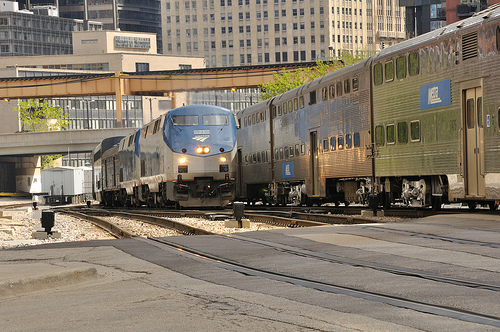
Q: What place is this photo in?
A: It is at the road.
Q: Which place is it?
A: It is a road.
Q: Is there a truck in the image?
A: Yes, there is a truck.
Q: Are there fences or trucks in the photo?
A: Yes, there is a truck.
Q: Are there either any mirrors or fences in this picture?
A: No, there are no fences or mirrors.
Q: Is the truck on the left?
A: Yes, the truck is on the left of the image.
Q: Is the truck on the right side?
A: No, the truck is on the left of the image.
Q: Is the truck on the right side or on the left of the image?
A: The truck is on the left of the image.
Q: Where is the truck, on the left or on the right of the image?
A: The truck is on the left of the image.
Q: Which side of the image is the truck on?
A: The truck is on the left of the image.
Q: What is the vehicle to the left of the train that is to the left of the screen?
A: The vehicle is a truck.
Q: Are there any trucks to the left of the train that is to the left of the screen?
A: Yes, there is a truck to the left of the train.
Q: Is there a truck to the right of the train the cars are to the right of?
A: No, the truck is to the left of the train.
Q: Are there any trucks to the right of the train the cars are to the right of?
A: No, the truck is to the left of the train.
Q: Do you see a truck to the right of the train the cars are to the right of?
A: No, the truck is to the left of the train.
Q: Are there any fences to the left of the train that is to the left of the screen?
A: No, there is a truck to the left of the train.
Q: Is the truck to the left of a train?
A: Yes, the truck is to the left of a train.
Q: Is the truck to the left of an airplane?
A: No, the truck is to the left of a train.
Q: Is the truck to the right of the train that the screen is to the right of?
A: No, the truck is to the left of the train.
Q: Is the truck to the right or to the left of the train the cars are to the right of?
A: The truck is to the left of the train.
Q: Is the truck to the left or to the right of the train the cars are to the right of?
A: The truck is to the left of the train.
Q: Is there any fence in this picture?
A: No, there are no fences.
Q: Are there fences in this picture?
A: No, there are no fences.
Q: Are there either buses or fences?
A: No, there are no fences or buses.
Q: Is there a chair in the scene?
A: No, there are no chairs.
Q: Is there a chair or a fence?
A: No, there are no chairs or fences.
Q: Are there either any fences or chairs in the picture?
A: No, there are no chairs or fences.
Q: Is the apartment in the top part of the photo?
A: Yes, the apartment is in the top of the image.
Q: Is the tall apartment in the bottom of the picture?
A: No, the apartment is in the top of the image.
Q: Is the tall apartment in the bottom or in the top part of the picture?
A: The apartment is in the top of the image.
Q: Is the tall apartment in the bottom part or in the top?
A: The apartment is in the top of the image.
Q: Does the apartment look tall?
A: Yes, the apartment is tall.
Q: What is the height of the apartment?
A: The apartment is tall.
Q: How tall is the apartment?
A: The apartment is tall.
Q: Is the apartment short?
A: No, the apartment is tall.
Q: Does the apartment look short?
A: No, the apartment is tall.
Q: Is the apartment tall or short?
A: The apartment is tall.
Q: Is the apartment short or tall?
A: The apartment is tall.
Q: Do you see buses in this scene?
A: No, there are no buses.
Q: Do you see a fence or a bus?
A: No, there are no buses or fences.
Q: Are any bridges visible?
A: Yes, there is a bridge.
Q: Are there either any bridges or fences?
A: Yes, there is a bridge.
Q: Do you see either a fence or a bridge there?
A: Yes, there is a bridge.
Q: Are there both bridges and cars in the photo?
A: Yes, there are both a bridge and a car.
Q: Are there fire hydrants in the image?
A: No, there are no fire hydrants.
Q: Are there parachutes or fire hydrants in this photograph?
A: No, there are no fire hydrants or parachutes.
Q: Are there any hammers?
A: No, there are no hammers.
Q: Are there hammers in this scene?
A: No, there are no hammers.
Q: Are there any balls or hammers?
A: No, there are no hammers or balls.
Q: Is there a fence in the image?
A: No, there are no fences.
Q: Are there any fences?
A: No, there are no fences.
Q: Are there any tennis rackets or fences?
A: No, there are no fences or tennis rackets.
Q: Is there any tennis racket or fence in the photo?
A: No, there are no fences or rackets.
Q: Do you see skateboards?
A: No, there are no skateboards.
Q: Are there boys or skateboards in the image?
A: No, there are no skateboards or boys.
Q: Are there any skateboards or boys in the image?
A: No, there are no skateboards or boys.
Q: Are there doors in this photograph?
A: Yes, there is a door.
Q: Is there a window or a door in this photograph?
A: Yes, there is a door.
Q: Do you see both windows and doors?
A: Yes, there are both a door and a window.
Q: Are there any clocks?
A: No, there are no clocks.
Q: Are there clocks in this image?
A: No, there are no clocks.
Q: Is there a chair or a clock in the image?
A: No, there are no clocks or chairs.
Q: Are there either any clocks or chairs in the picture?
A: No, there are no clocks or chairs.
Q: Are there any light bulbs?
A: No, there are no light bulbs.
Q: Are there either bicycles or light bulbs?
A: No, there are no light bulbs or bicycles.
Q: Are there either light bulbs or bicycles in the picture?
A: No, there are no light bulbs or bicycles.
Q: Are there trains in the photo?
A: Yes, there are trains.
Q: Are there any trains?
A: Yes, there are trains.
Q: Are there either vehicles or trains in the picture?
A: Yes, there are trains.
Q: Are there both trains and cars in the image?
A: Yes, there are both trains and a car.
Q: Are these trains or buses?
A: These are trains.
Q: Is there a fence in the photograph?
A: No, there are no fences.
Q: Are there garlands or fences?
A: No, there are no fences or garlands.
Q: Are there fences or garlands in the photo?
A: No, there are no fences or garlands.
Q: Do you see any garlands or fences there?
A: No, there are no fences or garlands.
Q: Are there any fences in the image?
A: No, there are no fences.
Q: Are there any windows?
A: Yes, there are windows.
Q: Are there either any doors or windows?
A: Yes, there are windows.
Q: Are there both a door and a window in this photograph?
A: Yes, there are both a window and a door.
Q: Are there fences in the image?
A: No, there are no fences.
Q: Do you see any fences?
A: No, there are no fences.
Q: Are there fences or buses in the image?
A: No, there are no fences or buses.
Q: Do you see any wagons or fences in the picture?
A: No, there are no fences or wagons.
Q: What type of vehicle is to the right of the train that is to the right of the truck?
A: The vehicles are cars.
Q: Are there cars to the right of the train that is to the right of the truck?
A: Yes, there are cars to the right of the train.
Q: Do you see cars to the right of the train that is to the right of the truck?
A: Yes, there are cars to the right of the train.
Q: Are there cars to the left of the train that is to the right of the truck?
A: No, the cars are to the right of the train.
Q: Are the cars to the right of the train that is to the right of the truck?
A: Yes, the cars are to the right of the train.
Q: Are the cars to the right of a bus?
A: No, the cars are to the right of the train.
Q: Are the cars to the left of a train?
A: No, the cars are to the right of a train.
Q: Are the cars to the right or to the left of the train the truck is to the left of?
A: The cars are to the right of the train.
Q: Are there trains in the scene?
A: Yes, there is a train.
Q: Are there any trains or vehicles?
A: Yes, there is a train.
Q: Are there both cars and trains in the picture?
A: Yes, there are both a train and a car.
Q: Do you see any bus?
A: No, there are no buses.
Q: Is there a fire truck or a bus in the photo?
A: No, there are no buses or fire trucks.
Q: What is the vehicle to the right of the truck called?
A: The vehicle is a train.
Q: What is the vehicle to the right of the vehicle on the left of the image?
A: The vehicle is a train.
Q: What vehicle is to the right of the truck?
A: The vehicle is a train.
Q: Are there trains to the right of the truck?
A: Yes, there is a train to the right of the truck.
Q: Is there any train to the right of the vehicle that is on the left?
A: Yes, there is a train to the right of the truck.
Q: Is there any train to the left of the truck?
A: No, the train is to the right of the truck.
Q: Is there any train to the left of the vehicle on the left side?
A: No, the train is to the right of the truck.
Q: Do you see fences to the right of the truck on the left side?
A: No, there is a train to the right of the truck.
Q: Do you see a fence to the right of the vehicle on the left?
A: No, there is a train to the right of the truck.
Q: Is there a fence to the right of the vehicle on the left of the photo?
A: No, there is a train to the right of the truck.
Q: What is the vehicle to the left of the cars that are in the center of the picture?
A: The vehicle is a train.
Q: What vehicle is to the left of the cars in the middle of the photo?
A: The vehicle is a train.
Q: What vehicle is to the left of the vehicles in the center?
A: The vehicle is a train.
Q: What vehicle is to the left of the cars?
A: The vehicle is a train.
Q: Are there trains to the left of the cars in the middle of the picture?
A: Yes, there is a train to the left of the cars.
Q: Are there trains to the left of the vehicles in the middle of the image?
A: Yes, there is a train to the left of the cars.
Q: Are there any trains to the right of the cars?
A: No, the train is to the left of the cars.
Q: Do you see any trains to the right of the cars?
A: No, the train is to the left of the cars.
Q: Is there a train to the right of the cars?
A: No, the train is to the left of the cars.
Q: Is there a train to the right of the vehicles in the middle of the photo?
A: No, the train is to the left of the cars.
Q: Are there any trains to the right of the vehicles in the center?
A: No, the train is to the left of the cars.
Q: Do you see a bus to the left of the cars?
A: No, there is a train to the left of the cars.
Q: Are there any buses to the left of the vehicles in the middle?
A: No, there is a train to the left of the cars.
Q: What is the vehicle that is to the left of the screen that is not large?
A: The vehicle is a train.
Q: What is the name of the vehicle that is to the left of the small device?
A: The vehicle is a train.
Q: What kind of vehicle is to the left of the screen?
A: The vehicle is a train.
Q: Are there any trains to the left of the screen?
A: Yes, there is a train to the left of the screen.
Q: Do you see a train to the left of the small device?
A: Yes, there is a train to the left of the screen.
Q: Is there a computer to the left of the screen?
A: No, there is a train to the left of the screen.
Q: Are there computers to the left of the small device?
A: No, there is a train to the left of the screen.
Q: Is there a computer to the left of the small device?
A: No, there is a train to the left of the screen.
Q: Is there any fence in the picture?
A: No, there are no fences.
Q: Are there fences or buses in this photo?
A: No, there are no fences or buses.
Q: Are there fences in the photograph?
A: No, there are no fences.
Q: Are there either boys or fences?
A: No, there are no fences or boys.